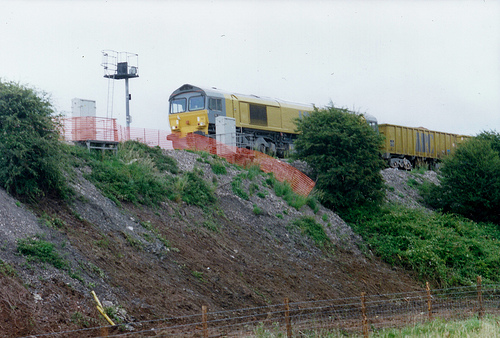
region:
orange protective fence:
[27, 97, 330, 214]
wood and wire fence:
[2, 280, 499, 335]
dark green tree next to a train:
[287, 94, 377, 221]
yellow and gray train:
[150, 67, 497, 194]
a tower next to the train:
[90, 29, 146, 152]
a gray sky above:
[210, 20, 480, 80]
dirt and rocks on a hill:
[116, 170, 345, 305]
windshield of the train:
[166, 90, 209, 115]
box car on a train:
[349, 107, 499, 174]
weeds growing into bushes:
[85, 142, 224, 222]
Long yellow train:
[165, 89, 499, 192]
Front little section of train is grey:
[173, 78, 231, 143]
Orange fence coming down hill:
[68, 114, 323, 206]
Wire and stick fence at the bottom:
[191, 275, 494, 337]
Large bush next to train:
[296, 103, 398, 237]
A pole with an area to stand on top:
[98, 43, 151, 144]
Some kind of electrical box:
[65, 88, 110, 147]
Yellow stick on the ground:
[84, 283, 126, 335]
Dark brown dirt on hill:
[68, 187, 414, 337]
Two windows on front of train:
[169, 91, 211, 113]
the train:
[150, 88, 422, 173]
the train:
[146, 85, 495, 255]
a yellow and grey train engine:
[169, 83, 377, 156]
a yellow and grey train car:
[376, 122, 498, 172]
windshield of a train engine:
[167, 93, 209, 113]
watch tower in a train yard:
[101, 49, 131, 142]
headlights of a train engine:
[168, 117, 206, 128]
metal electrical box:
[214, 113, 236, 155]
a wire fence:
[21, 273, 498, 335]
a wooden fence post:
[359, 292, 369, 336]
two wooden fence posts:
[424, 276, 484, 321]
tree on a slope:
[291, 106, 388, 205]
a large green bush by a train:
[303, 117, 390, 214]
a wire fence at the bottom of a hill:
[158, 294, 498, 335]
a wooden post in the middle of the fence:
[353, 291, 369, 336]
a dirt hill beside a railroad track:
[3, 148, 490, 290]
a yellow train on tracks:
[166, 84, 496, 185]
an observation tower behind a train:
[93, 42, 145, 125]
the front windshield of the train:
[166, 87, 201, 113]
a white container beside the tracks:
[208, 111, 239, 152]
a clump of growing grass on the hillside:
[369, 201, 498, 281]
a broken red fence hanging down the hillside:
[86, 119, 318, 201]